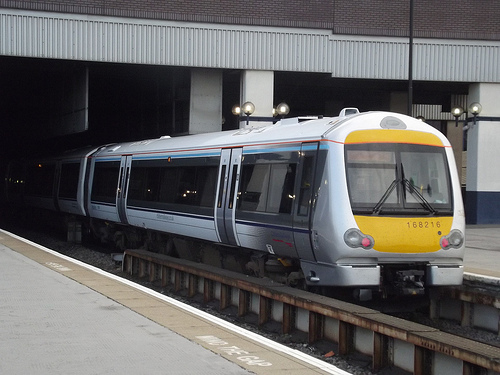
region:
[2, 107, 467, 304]
Train on a rusty track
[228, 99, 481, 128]
Street lamps at the station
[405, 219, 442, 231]
Number on the front of the train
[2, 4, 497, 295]
Train exiting a large building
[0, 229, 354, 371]
Warning barrier beside track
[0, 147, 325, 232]
Window tint on the sides of the train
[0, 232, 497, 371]
Loose gravel around track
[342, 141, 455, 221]
Windshield of the train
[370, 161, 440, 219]
Windshield wipers on train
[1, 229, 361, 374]
Sidewalk for passengers to wait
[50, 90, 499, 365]
a train in motion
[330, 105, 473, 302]
front of train si white and yellow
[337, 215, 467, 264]
headlights of train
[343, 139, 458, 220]
two wipes on a windshild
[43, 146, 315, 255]
doors of train are color silver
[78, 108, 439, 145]
roof of train is white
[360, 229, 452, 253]
red lights on front of train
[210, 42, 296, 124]
lights in front column of tunnel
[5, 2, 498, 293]
train is coming out a tunnel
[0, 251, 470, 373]
a platform next to railroad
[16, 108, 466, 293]
Train exiting the dark tunnel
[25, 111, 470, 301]
Train is mostly grey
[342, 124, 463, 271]
train has a yellow face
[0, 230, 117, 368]
Cement platform next to train tracks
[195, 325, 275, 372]
White writing on train platform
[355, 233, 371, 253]
Red light on front of train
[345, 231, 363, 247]
White light on front of train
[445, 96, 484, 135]
Lighting for platform behind train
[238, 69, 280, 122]
Cemment pillars behind the train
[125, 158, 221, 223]
passenger windows on the train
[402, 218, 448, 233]
black numbers on the yellow front of the train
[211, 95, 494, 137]
lights over the train platform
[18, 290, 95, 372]
grey concrete surface of the platform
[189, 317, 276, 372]
white lettering on the concrete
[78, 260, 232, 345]
tan concrete divider of the platform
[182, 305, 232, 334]
white stripe on the edge of the platform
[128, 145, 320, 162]
blue stripe on the side of the train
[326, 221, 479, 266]
headlights on the front of the train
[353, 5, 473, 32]
brown brick surface of the train stattion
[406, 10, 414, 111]
black metal pipe attached to the building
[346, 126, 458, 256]
the yellow front of a train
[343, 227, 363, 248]
a headlight on a train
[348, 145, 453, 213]
the front windshield on a train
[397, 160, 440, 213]
a windshield wiper on a train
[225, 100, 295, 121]
lights at a train station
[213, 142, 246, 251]
a double door on a train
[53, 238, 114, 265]
gravel along the tracks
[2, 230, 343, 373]
a platform at a train station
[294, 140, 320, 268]
a single door near the front of a train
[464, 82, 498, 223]
a pillar at a train station